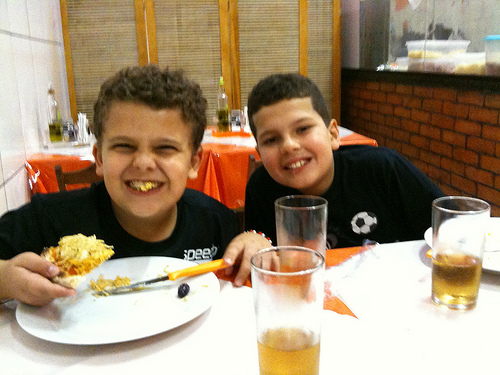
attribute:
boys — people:
[1, 64, 454, 308]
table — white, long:
[0, 237, 500, 374]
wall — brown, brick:
[343, 74, 500, 217]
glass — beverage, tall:
[251, 247, 323, 373]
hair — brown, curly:
[95, 66, 208, 157]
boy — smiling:
[244, 73, 462, 249]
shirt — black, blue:
[243, 146, 459, 247]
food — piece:
[41, 234, 116, 279]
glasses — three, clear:
[249, 196, 499, 373]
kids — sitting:
[1, 66, 460, 308]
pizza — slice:
[41, 232, 116, 281]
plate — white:
[14, 254, 221, 346]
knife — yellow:
[89, 257, 232, 294]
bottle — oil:
[217, 76, 230, 137]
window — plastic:
[386, 2, 498, 62]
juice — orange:
[256, 325, 322, 373]